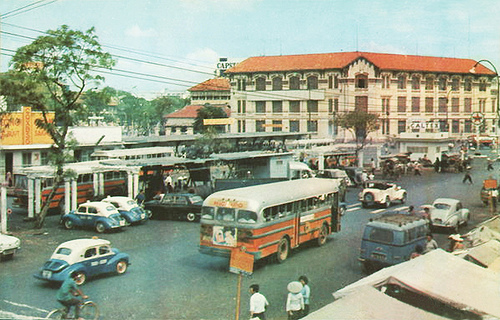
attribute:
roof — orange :
[226, 51, 494, 77]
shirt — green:
[48, 282, 80, 304]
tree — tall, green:
[2, 23, 112, 195]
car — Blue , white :
[33, 228, 142, 293]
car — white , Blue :
[31, 235, 131, 287]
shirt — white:
[246, 292, 268, 315]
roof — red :
[387, 52, 439, 68]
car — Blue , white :
[25, 212, 121, 282]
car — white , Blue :
[44, 235, 151, 293]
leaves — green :
[28, 23, 85, 60]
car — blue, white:
[31, 230, 129, 285]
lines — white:
[343, 196, 437, 219]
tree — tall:
[0, 20, 122, 230]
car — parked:
[60, 199, 131, 232]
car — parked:
[101, 195, 149, 225]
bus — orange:
[192, 173, 339, 260]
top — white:
[202, 176, 342, 210]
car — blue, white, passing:
[45, 239, 132, 285]